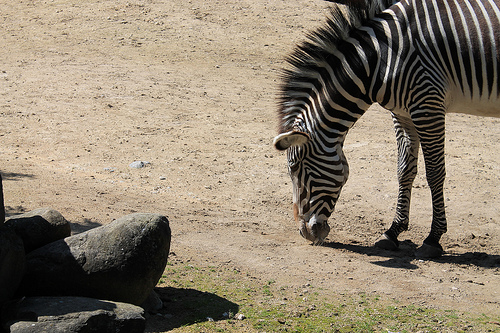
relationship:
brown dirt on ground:
[0, 0, 499, 333] [110, 52, 207, 82]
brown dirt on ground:
[0, 0, 499, 333] [2, 0, 496, 332]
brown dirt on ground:
[0, 0, 499, 333] [9, 5, 475, 293]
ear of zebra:
[271, 128, 309, 151] [205, 0, 497, 217]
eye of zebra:
[290, 163, 300, 173] [267, 2, 499, 267]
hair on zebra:
[276, 1, 379, 136] [267, 2, 499, 267]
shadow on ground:
[329, 245, 499, 272] [2, 0, 496, 332]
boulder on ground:
[2, 210, 173, 313] [3, 2, 498, 254]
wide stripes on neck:
[296, 17, 382, 138] [285, 13, 373, 132]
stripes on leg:
[378, 72, 413, 95] [414, 119, 449, 230]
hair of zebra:
[276, 1, 379, 136] [291, 2, 498, 243]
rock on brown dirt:
[127, 160, 148, 170] [0, 0, 499, 333]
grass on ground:
[245, 285, 325, 331] [217, 225, 317, 311]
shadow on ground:
[329, 245, 499, 272] [337, 256, 489, 327]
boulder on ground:
[2, 210, 173, 313] [2, 0, 496, 332]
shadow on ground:
[160, 278, 230, 321] [210, 262, 294, 317]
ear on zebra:
[271, 125, 310, 157] [267, 2, 499, 267]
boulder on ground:
[33, 210, 173, 303] [2, 0, 496, 332]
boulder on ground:
[2, 201, 71, 250] [2, 0, 496, 332]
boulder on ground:
[35, 293, 152, 320] [2, 0, 496, 332]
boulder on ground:
[8, 307, 116, 332] [2, 0, 496, 332]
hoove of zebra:
[415, 244, 446, 264] [267, 2, 499, 267]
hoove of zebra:
[370, 232, 398, 251] [267, 2, 499, 267]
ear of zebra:
[271, 128, 309, 151] [267, 2, 499, 267]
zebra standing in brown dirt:
[267, 2, 499, 267] [0, 0, 499, 333]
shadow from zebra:
[329, 245, 428, 272] [259, 36, 381, 258]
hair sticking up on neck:
[260, 37, 359, 88] [268, 37, 375, 165]